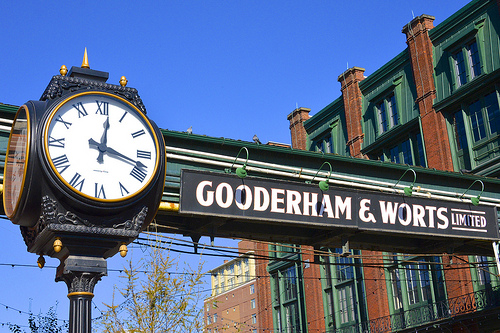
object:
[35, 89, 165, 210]
clock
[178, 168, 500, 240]
sign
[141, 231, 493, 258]
cable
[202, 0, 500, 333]
building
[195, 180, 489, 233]
name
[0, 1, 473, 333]
sky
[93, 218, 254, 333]
plant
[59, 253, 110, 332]
post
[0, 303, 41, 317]
branch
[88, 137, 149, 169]
hands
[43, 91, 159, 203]
face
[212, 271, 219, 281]
window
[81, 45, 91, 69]
post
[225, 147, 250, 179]
light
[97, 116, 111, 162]
hand